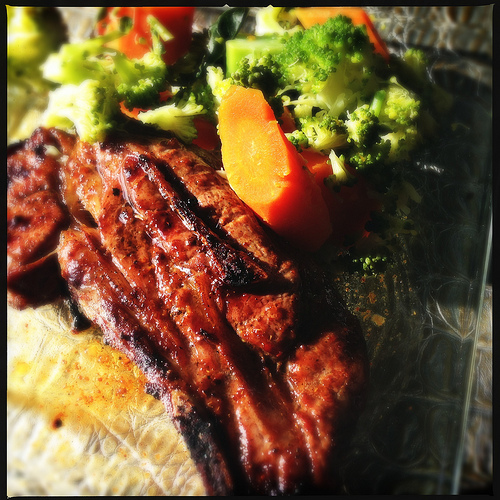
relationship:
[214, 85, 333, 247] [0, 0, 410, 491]
carrot on meal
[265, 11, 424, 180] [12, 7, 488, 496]
broccoli on plate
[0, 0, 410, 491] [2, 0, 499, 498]
meal on tray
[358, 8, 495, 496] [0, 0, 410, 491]
background of meal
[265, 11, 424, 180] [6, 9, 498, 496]
broccoli part of meal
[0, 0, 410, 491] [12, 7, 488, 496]
meal on plate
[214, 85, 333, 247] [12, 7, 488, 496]
carrot on plate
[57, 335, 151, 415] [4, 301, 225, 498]
sauce on bread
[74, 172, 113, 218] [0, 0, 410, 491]
color on meal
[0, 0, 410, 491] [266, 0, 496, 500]
meal on plate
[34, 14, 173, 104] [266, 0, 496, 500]
broccoli on plate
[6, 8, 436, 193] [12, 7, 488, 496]
broccoli on plate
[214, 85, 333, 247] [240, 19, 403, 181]
carrot and broccoli